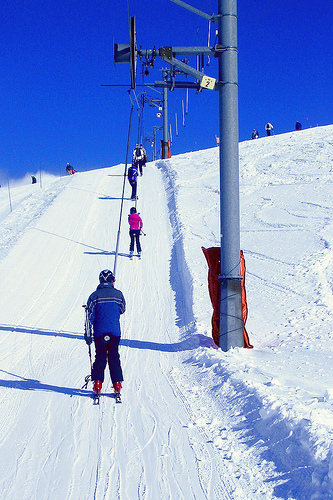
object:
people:
[265, 121, 274, 136]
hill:
[0, 122, 333, 187]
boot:
[93, 380, 103, 395]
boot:
[113, 381, 122, 394]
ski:
[93, 395, 99, 405]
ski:
[115, 393, 122, 403]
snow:
[0, 272, 65, 497]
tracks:
[0, 129, 331, 498]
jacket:
[128, 213, 143, 231]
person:
[128, 162, 139, 199]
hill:
[78, 149, 219, 474]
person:
[128, 206, 144, 257]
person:
[65, 162, 77, 174]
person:
[140, 143, 146, 165]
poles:
[215, 0, 244, 352]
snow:
[265, 160, 327, 227]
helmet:
[99, 268, 117, 284]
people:
[83, 270, 126, 396]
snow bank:
[138, 258, 332, 499]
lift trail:
[0, 158, 329, 496]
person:
[132, 142, 144, 177]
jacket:
[128, 165, 139, 181]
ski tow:
[104, 69, 172, 133]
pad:
[200, 244, 254, 350]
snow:
[18, 152, 258, 365]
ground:
[0, 159, 333, 500]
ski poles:
[82, 304, 94, 371]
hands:
[83, 331, 92, 345]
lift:
[132, 142, 146, 166]